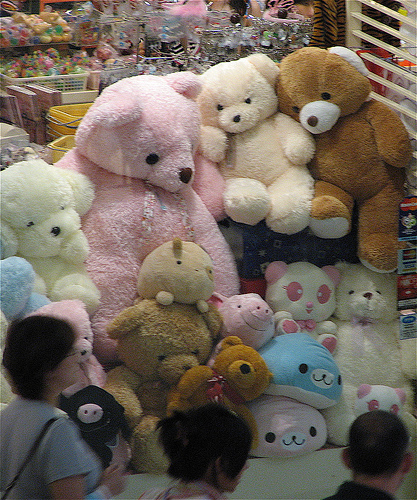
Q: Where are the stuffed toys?
A: In the stores.